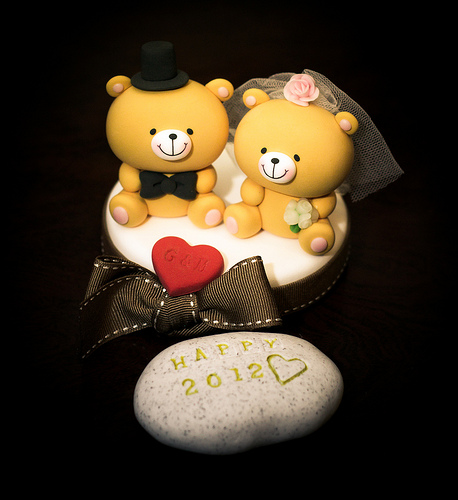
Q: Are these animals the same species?
A: Yes, all the animals are bears.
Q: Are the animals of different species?
A: No, all the animals are bears.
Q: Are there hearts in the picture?
A: Yes, there is a heart.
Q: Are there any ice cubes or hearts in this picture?
A: Yes, there is a heart.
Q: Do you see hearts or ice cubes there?
A: Yes, there is a heart.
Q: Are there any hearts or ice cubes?
A: Yes, there is a heart.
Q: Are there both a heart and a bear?
A: Yes, there are both a heart and a bear.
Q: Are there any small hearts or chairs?
A: Yes, there is a small heart.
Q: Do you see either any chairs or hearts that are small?
A: Yes, the heart is small.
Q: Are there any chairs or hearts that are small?
A: Yes, the heart is small.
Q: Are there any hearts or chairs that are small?
A: Yes, the heart is small.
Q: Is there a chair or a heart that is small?
A: Yes, the heart is small.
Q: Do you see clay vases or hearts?
A: Yes, there is a clay heart.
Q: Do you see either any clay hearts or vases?
A: Yes, there is a clay heart.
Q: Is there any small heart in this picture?
A: Yes, there is a small heart.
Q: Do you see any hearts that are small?
A: Yes, there is a heart that is small.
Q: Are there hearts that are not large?
A: Yes, there is a small heart.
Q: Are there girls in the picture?
A: No, there are no girls.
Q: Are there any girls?
A: No, there are no girls.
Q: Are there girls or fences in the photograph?
A: No, there are no girls or fences.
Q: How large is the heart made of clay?
A: The heart is small.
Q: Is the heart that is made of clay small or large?
A: The heart is small.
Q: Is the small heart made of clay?
A: Yes, the heart is made of clay.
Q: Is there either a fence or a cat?
A: No, there are no fences or cats.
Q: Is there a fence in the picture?
A: No, there are no fences.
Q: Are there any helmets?
A: No, there are no helmets.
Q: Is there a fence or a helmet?
A: No, there are no helmets or fences.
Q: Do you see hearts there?
A: Yes, there is a heart.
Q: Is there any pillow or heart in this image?
A: Yes, there is a heart.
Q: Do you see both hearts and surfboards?
A: No, there is a heart but no surfboards.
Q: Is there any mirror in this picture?
A: No, there are no mirrors.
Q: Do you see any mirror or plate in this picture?
A: No, there are no mirrors or plates.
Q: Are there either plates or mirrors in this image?
A: No, there are no mirrors or plates.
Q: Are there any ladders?
A: No, there are no ladders.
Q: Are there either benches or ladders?
A: No, there are no ladders or benches.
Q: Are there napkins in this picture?
A: No, there are no napkins.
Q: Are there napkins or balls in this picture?
A: No, there are no napkins or balls.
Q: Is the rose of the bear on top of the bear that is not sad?
A: Yes, the rose is on top of the bear.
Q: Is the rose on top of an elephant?
A: No, the rose is on top of the bear.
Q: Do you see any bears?
A: Yes, there is a bear.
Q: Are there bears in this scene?
A: Yes, there is a bear.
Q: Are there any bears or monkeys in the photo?
A: Yes, there is a bear.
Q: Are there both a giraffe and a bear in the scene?
A: No, there is a bear but no giraffes.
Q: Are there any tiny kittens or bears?
A: Yes, there is a tiny bear.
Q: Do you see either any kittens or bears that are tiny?
A: Yes, the bear is tiny.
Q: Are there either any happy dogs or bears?
A: Yes, there is a happy bear.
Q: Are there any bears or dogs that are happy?
A: Yes, the bear is happy.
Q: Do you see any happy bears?
A: Yes, there is a happy bear.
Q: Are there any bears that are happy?
A: Yes, there is a bear that is happy.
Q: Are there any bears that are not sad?
A: Yes, there is a happy bear.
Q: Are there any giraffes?
A: No, there are no giraffes.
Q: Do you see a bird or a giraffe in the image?
A: No, there are no giraffes or birds.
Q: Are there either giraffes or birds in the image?
A: No, there are no giraffes or birds.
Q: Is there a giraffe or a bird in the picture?
A: No, there are no giraffes or birds.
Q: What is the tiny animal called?
A: The animal is a bear.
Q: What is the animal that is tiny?
A: The animal is a bear.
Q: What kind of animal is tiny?
A: The animal is a bear.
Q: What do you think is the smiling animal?
A: The animal is a bear.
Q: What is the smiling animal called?
A: The animal is a bear.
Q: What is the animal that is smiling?
A: The animal is a bear.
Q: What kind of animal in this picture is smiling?
A: The animal is a bear.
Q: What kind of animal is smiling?
A: The animal is a bear.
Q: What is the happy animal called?
A: The animal is a bear.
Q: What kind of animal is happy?
A: The animal is a bear.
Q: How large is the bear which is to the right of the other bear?
A: The bear is tiny.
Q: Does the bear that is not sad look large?
A: No, the bear is tiny.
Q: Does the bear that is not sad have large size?
A: No, the bear is tiny.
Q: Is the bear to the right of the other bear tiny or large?
A: The bear is tiny.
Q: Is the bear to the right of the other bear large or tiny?
A: The bear is tiny.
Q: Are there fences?
A: No, there are no fences.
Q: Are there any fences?
A: No, there are no fences.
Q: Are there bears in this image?
A: Yes, there is a bear.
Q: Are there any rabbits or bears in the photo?
A: Yes, there is a bear.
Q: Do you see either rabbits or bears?
A: Yes, there is a bear.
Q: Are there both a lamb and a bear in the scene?
A: No, there is a bear but no lambs.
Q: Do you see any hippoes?
A: No, there are no hippoes.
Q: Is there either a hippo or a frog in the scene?
A: No, there are no hippoes or frogs.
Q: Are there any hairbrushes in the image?
A: No, there are no hairbrushes.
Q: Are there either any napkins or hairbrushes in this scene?
A: No, there are no hairbrushes or napkins.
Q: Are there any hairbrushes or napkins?
A: No, there are no hairbrushes or napkins.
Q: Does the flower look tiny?
A: Yes, the flower is tiny.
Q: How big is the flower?
A: The flower is tiny.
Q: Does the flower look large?
A: No, the flower is tiny.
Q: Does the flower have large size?
A: No, the flower is tiny.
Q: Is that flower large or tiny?
A: The flower is tiny.